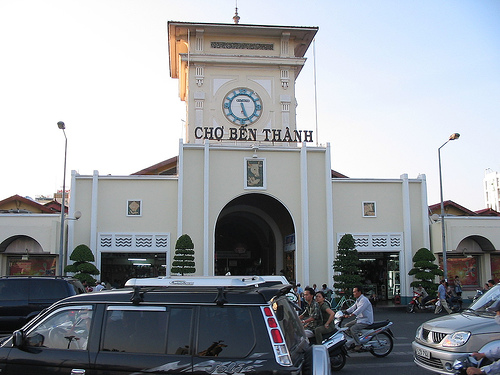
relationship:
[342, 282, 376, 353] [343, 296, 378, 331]
man in shirt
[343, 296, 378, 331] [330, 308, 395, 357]
shirt on motorbike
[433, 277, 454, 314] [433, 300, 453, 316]
man walking in pants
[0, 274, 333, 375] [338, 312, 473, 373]
black suv on street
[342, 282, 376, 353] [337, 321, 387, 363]
man on bikes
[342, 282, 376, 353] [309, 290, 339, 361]
man on bikes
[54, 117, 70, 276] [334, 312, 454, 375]
light pole on road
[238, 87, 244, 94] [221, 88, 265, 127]
number on clock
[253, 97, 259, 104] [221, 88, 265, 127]
number on clock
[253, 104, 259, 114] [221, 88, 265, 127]
number on clock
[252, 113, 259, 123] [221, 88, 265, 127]
number on clock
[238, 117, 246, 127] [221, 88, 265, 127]
number on clock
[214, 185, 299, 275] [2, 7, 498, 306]
arch in building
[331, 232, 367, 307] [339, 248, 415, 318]
topiaries by entrance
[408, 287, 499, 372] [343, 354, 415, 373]
gray vehicle on street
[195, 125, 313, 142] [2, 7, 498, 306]
writing on building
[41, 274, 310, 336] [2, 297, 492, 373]
black suv on foreground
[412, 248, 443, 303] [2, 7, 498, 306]
topiaries outside building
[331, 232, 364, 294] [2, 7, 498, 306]
topiaries outside building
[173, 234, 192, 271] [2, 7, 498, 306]
topiaries outside building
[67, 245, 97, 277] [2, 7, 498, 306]
topiaries outside building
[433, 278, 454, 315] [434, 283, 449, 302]
man walking in shirt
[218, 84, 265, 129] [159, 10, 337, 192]
clock face in building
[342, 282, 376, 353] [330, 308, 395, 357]
man on motorbike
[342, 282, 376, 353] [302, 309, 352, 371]
man on bike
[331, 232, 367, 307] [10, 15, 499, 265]
topiaries in front of building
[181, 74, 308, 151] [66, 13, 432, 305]
clock on building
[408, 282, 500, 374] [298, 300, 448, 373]
gray vehicle on road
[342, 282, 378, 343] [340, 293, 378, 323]
man with shirt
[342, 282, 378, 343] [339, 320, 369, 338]
man with pants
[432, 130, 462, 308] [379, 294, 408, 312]
light on sidewalk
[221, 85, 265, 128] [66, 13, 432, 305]
clock on building